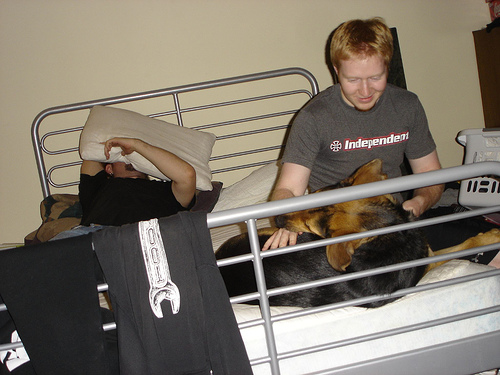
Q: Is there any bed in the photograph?
A: Yes, there is a bed.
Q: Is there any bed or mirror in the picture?
A: Yes, there is a bed.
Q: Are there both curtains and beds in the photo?
A: No, there is a bed but no curtains.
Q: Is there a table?
A: No, there are no tables.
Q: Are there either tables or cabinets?
A: No, there are no tables or cabinets.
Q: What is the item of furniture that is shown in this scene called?
A: The piece of furniture is a bed.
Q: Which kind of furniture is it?
A: The piece of furniture is a bed.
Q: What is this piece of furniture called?
A: This is a bed.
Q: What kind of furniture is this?
A: This is a bed.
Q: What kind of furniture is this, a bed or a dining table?
A: This is a bed.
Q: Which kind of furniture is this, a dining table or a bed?
A: This is a bed.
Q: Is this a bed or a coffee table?
A: This is a bed.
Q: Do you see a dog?
A: Yes, there is a dog.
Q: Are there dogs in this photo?
A: Yes, there is a dog.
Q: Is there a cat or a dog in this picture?
A: Yes, there is a dog.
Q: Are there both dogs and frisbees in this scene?
A: No, there is a dog but no frisbees.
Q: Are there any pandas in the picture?
A: No, there are no pandas.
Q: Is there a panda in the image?
A: No, there are no pandas.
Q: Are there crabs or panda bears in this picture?
A: No, there are no panda bears or crabs.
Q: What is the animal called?
A: The animal is a dog.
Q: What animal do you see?
A: The animal is a dog.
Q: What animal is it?
A: The animal is a dog.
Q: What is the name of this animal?
A: This is a dog.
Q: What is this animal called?
A: This is a dog.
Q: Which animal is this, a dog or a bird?
A: This is a dog.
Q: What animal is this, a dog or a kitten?
A: This is a dog.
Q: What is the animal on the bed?
A: The animal is a dog.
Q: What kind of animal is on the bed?
A: The animal is a dog.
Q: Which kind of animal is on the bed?
A: The animal is a dog.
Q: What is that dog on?
A: The dog is on the bed.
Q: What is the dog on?
A: The dog is on the bed.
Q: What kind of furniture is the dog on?
A: The dog is on the bed.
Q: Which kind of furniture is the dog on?
A: The dog is on the bed.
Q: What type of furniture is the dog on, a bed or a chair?
A: The dog is on a bed.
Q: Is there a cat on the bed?
A: No, there is a dog on the bed.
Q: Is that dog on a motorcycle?
A: No, the dog is on a bed.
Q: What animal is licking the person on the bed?
A: The dog is licking the man.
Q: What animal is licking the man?
A: The dog is licking the man.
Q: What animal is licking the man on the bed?
A: The animal is a dog.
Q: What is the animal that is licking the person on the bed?
A: The animal is a dog.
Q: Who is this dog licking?
A: The dog is licking the man.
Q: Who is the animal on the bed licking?
A: The dog is licking the man.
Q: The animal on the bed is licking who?
A: The dog is licking the man.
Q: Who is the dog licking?
A: The dog is licking the man.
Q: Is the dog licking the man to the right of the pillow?
A: Yes, the dog is licking the man.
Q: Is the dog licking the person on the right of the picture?
A: Yes, the dog is licking the man.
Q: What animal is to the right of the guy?
A: The animal is a dog.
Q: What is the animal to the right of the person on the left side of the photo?
A: The animal is a dog.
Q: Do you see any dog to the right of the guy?
A: Yes, there is a dog to the right of the guy.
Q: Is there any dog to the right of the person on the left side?
A: Yes, there is a dog to the right of the guy.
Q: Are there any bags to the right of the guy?
A: No, there is a dog to the right of the guy.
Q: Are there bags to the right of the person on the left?
A: No, there is a dog to the right of the guy.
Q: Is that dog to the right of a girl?
A: No, the dog is to the right of a guy.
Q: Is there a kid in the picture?
A: No, there are no children.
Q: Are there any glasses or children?
A: No, there are no children or glasses.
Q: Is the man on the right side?
A: Yes, the man is on the right of the image.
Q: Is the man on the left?
A: No, the man is on the right of the image.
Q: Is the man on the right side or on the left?
A: The man is on the right of the image.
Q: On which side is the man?
A: The man is on the right of the image.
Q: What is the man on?
A: The man is on the bed.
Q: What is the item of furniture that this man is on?
A: The piece of furniture is a bed.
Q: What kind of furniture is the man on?
A: The man is on the bed.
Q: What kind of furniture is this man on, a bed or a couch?
A: The man is on a bed.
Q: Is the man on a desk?
A: No, the man is on the bed.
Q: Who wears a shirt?
A: The man wears a shirt.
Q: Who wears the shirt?
A: The man wears a shirt.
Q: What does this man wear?
A: The man wears a shirt.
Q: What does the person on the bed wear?
A: The man wears a shirt.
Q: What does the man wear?
A: The man wears a shirt.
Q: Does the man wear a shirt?
A: Yes, the man wears a shirt.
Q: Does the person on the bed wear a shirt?
A: Yes, the man wears a shirt.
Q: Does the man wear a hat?
A: No, the man wears a shirt.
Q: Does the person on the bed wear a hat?
A: No, the man wears a shirt.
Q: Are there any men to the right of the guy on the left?
A: Yes, there is a man to the right of the guy.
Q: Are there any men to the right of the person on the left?
A: Yes, there is a man to the right of the guy.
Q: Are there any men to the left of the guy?
A: No, the man is to the right of the guy.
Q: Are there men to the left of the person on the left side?
A: No, the man is to the right of the guy.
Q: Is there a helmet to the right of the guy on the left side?
A: No, there is a man to the right of the guy.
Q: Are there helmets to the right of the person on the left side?
A: No, there is a man to the right of the guy.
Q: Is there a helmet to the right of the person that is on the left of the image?
A: No, there is a man to the right of the guy.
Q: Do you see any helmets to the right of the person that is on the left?
A: No, there is a man to the right of the guy.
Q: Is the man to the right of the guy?
A: Yes, the man is to the right of the guy.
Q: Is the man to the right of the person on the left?
A: Yes, the man is to the right of the guy.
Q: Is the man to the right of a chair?
A: No, the man is to the right of the guy.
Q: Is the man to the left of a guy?
A: No, the man is to the right of a guy.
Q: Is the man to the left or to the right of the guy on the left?
A: The man is to the right of the guy.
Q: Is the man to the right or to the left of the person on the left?
A: The man is to the right of the guy.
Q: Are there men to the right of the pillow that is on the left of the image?
A: Yes, there is a man to the right of the pillow.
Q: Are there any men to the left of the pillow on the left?
A: No, the man is to the right of the pillow.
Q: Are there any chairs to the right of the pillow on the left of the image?
A: No, there is a man to the right of the pillow.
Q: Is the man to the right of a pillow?
A: Yes, the man is to the right of a pillow.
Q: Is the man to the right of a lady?
A: No, the man is to the right of a pillow.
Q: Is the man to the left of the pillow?
A: No, the man is to the right of the pillow.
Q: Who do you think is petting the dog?
A: The man is petting the dog.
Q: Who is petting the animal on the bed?
A: The man is petting the dog.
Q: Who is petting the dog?
A: The man is petting the dog.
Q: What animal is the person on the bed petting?
A: The man is petting the dog.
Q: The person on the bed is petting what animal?
A: The man is petting the dog.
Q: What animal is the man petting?
A: The man is petting the dog.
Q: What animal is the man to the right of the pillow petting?
A: The man is petting the dog.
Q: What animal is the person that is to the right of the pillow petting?
A: The man is petting the dog.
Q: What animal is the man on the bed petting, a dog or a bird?
A: The man is petting a dog.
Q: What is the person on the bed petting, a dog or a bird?
A: The man is petting a dog.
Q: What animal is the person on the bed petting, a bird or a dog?
A: The man is petting a dog.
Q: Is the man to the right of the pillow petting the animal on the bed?
A: Yes, the man is petting the dog.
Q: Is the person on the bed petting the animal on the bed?
A: Yes, the man is petting the dog.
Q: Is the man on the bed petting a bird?
A: No, the man is petting the dog.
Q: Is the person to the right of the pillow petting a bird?
A: No, the man is petting the dog.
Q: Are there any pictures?
A: No, there are no pictures.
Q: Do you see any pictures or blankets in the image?
A: No, there are no pictures or blankets.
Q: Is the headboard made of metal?
A: Yes, the headboard is made of metal.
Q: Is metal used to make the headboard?
A: Yes, the headboard is made of metal.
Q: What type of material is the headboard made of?
A: The headboard is made of metal.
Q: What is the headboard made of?
A: The headboard is made of metal.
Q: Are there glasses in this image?
A: No, there are no glasses.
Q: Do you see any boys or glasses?
A: No, there are no glasses or boys.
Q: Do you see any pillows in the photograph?
A: Yes, there is a pillow.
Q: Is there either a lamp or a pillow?
A: Yes, there is a pillow.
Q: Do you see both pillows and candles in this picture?
A: No, there is a pillow but no candles.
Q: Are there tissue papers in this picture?
A: No, there are no tissue papers.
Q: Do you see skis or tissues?
A: No, there are no tissues or skis.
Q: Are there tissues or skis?
A: No, there are no tissues or skis.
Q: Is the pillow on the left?
A: Yes, the pillow is on the left of the image.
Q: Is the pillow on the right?
A: No, the pillow is on the left of the image.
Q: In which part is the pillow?
A: The pillow is on the left of the image.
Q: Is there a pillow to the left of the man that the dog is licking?
A: Yes, there is a pillow to the left of the man.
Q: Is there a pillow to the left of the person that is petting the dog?
A: Yes, there is a pillow to the left of the man.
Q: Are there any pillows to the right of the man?
A: No, the pillow is to the left of the man.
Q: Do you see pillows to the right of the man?
A: No, the pillow is to the left of the man.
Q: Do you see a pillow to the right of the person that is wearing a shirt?
A: No, the pillow is to the left of the man.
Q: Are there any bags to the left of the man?
A: No, there is a pillow to the left of the man.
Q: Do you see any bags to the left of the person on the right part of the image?
A: No, there is a pillow to the left of the man.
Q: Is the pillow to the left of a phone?
A: No, the pillow is to the left of a man.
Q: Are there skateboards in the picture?
A: No, there are no skateboards.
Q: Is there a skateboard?
A: No, there are no skateboards.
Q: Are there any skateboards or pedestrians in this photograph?
A: No, there are no skateboards or pedestrians.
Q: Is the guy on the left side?
A: Yes, the guy is on the left of the image.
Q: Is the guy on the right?
A: No, the guy is on the left of the image.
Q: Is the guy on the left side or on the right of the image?
A: The guy is on the left of the image.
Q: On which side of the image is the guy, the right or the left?
A: The guy is on the left of the image.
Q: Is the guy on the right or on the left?
A: The guy is on the left of the image.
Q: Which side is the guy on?
A: The guy is on the left of the image.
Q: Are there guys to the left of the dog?
A: Yes, there is a guy to the left of the dog.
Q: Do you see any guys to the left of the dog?
A: Yes, there is a guy to the left of the dog.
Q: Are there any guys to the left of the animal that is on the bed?
A: Yes, there is a guy to the left of the dog.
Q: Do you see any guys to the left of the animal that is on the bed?
A: Yes, there is a guy to the left of the dog.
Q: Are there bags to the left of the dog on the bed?
A: No, there is a guy to the left of the dog.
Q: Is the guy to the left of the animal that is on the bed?
A: Yes, the guy is to the left of the dog.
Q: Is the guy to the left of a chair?
A: No, the guy is to the left of the dog.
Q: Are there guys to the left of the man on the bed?
A: Yes, there is a guy to the left of the man.